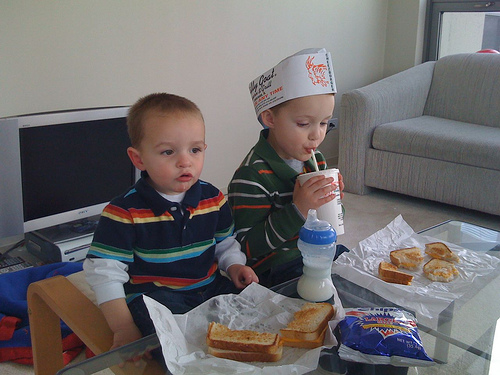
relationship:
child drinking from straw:
[226, 43, 415, 375] [306, 146, 321, 174]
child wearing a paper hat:
[226, 43, 415, 375] [238, 43, 339, 130]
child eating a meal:
[81, 91, 262, 369] [201, 295, 335, 365]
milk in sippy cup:
[297, 258, 336, 303] [296, 208, 337, 304]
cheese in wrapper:
[377, 264, 412, 281] [333, 214, 500, 321]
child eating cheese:
[226, 43, 415, 375] [377, 264, 412, 281]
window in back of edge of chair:
[431, 8, 500, 62] [336, 50, 498, 220]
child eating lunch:
[226, 43, 415, 375] [334, 214, 500, 321]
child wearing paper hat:
[226, 43, 415, 375] [238, 43, 339, 130]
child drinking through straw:
[226, 43, 415, 375] [306, 146, 321, 174]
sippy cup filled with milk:
[296, 208, 337, 304] [297, 258, 336, 303]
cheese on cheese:
[377, 271, 413, 283] [377, 264, 412, 281]